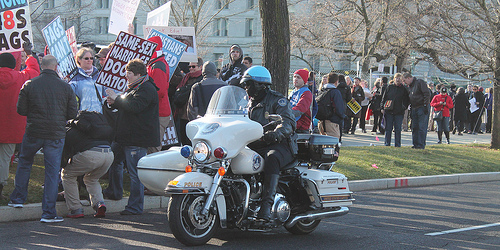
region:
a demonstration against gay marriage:
[21, 15, 463, 227]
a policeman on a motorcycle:
[139, 66, 359, 237]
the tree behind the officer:
[252, 0, 293, 101]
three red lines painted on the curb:
[390, 174, 421, 196]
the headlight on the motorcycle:
[189, 136, 214, 171]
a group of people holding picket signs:
[12, 8, 193, 206]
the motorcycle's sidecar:
[132, 135, 189, 197]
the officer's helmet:
[237, 55, 277, 94]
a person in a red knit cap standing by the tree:
[290, 62, 312, 139]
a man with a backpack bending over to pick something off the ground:
[56, 106, 117, 225]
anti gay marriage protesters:
[43, 10, 189, 113]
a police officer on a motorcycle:
[160, 67, 358, 244]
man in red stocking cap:
[280, 62, 321, 142]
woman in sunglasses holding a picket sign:
[41, 18, 104, 113]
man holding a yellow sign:
[344, 67, 369, 142]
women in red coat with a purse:
[427, 74, 458, 159]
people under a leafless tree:
[370, 0, 497, 158]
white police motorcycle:
[161, 80, 311, 247]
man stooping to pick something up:
[50, 96, 120, 240]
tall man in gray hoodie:
[221, 34, 246, 128]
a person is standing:
[401, 70, 434, 150]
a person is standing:
[13, 53, 74, 225]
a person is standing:
[1, 44, 38, 181]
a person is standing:
[106, 59, 155, 224]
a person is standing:
[66, 43, 112, 113]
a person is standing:
[188, 55, 229, 121]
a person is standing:
[217, 38, 247, 80]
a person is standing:
[287, 60, 310, 136]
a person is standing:
[318, 73, 343, 144]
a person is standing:
[374, 65, 401, 147]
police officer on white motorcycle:
[241, 65, 298, 230]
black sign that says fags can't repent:
[42, 14, 78, 83]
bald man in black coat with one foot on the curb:
[15, 53, 62, 223]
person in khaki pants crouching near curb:
[60, 108, 112, 218]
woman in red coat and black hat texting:
[430, 86, 452, 143]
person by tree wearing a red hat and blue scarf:
[288, 66, 316, 135]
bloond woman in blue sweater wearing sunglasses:
[67, 46, 108, 116]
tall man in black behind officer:
[219, 43, 246, 85]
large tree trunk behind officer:
[257, 1, 291, 99]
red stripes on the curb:
[393, 177, 408, 186]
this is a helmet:
[243, 66, 269, 79]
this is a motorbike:
[159, 142, 257, 217]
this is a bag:
[79, 107, 109, 132]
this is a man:
[116, 61, 152, 151]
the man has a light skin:
[128, 75, 133, 79]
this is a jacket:
[27, 76, 67, 133]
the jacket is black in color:
[33, 90, 67, 125]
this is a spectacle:
[83, 56, 94, 60]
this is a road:
[386, 182, 491, 248]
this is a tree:
[423, 0, 492, 62]